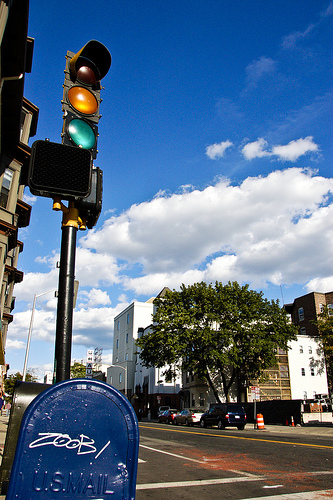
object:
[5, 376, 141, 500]
post box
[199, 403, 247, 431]
car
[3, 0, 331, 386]
sky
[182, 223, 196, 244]
clouds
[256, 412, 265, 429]
traffic cone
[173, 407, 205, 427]
car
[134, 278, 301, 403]
tree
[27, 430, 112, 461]
graffiti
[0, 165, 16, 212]
window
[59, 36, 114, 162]
light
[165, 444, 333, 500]
dirt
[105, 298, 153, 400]
building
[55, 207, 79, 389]
pole